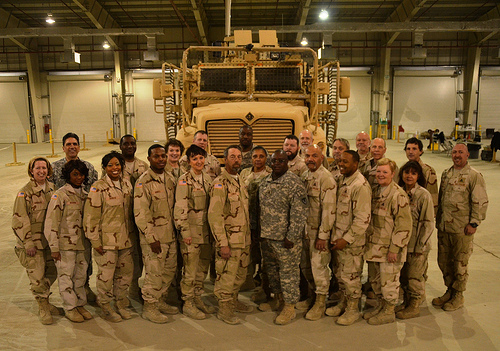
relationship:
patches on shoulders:
[15, 190, 28, 199] [13, 180, 38, 200]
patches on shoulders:
[50, 192, 60, 197] [46, 181, 70, 207]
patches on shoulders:
[87, 183, 97, 193] [84, 173, 111, 200]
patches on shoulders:
[130, 180, 146, 190] [130, 166, 158, 193]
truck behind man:
[153, 29, 350, 162] [255, 149, 307, 325]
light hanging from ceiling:
[45, 12, 56, 25] [1, 0, 485, 67]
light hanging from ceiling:
[101, 39, 110, 51] [1, 0, 485, 67]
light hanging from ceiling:
[301, 37, 308, 45] [1, 0, 485, 67]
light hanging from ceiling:
[319, 10, 331, 22] [1, 0, 485, 67]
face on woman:
[32, 157, 49, 182] [10, 157, 62, 324]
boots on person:
[365, 299, 397, 323] [364, 159, 413, 326]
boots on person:
[297, 287, 325, 316] [300, 144, 336, 321]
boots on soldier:
[254, 291, 302, 321] [252, 140, 305, 326]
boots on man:
[212, 291, 260, 323] [209, 145, 260, 325]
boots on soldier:
[178, 288, 216, 319] [173, 138, 220, 315]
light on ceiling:
[320, 12, 343, 32] [10, 5, 484, 74]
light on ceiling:
[301, 37, 308, 45] [10, 5, 484, 74]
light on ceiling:
[101, 39, 110, 51] [10, 5, 484, 74]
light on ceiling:
[45, 12, 56, 25] [10, 5, 484, 74]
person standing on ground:
[10, 155, 57, 325] [2, 142, 477, 345]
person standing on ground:
[430, 142, 480, 311] [2, 142, 477, 345]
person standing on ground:
[16, 155, 56, 325] [2, 142, 477, 345]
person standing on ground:
[401, 162, 434, 311] [2, 142, 477, 345]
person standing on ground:
[297, 141, 331, 316] [2, 142, 477, 345]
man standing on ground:
[255, 149, 307, 325] [2, 142, 477, 345]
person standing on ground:
[395, 162, 436, 319] [0, 221, 500, 349]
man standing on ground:
[255, 149, 307, 325] [0, 315, 498, 348]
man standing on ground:
[209, 145, 260, 325] [0, 304, 498, 349]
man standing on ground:
[209, 145, 260, 325] [2, 142, 477, 345]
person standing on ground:
[300, 144, 336, 321] [2, 142, 477, 345]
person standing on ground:
[364, 159, 411, 326] [2, 142, 477, 345]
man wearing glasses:
[255, 146, 305, 326] [267, 155, 285, 162]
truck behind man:
[153, 22, 356, 163] [255, 149, 307, 325]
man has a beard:
[209, 145, 260, 325] [226, 164, 247, 178]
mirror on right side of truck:
[337, 74, 354, 101] [153, 22, 356, 163]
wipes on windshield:
[195, 79, 309, 105] [193, 62, 308, 95]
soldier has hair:
[173, 143, 213, 320] [187, 143, 205, 160]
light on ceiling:
[319, 10, 331, 22] [10, 5, 484, 74]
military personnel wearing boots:
[12, 128, 489, 323] [30, 282, 480, 322]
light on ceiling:
[319, 10, 331, 22] [11, 8, 489, 78]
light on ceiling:
[301, 35, 308, 45] [11, 8, 489, 78]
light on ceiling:
[101, 39, 110, 49] [11, 8, 489, 78]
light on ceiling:
[46, 12, 56, 24] [11, 8, 489, 78]